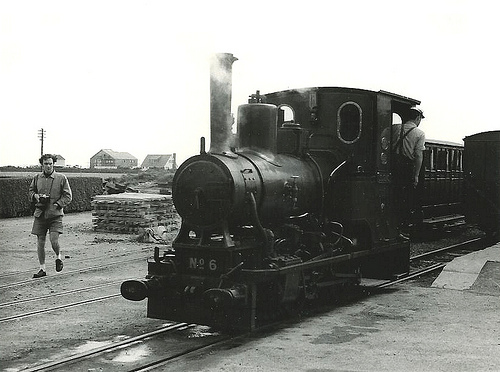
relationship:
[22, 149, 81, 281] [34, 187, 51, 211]
man holding camera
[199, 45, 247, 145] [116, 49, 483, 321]
steam coming from train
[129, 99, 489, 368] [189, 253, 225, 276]
engine has number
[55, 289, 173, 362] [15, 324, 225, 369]
track in front of train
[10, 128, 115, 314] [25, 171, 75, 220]
man wearing wears coat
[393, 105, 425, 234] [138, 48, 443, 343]
train conductor on engine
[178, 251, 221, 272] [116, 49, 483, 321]
white letters on train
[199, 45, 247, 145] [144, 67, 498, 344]
steam from train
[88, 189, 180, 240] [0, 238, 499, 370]
wood near tracks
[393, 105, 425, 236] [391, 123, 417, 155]
conductor wearing suspenders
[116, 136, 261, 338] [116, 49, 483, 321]
front of train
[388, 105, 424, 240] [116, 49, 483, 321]
person in train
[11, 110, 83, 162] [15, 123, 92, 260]
pole behind man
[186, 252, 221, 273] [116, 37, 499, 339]
word painted on train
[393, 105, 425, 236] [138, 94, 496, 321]
conductor standing outside of train